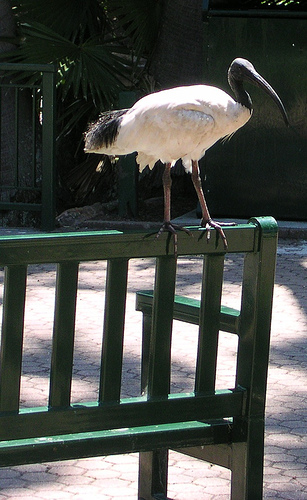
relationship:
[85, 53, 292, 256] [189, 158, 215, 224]
bird has leg